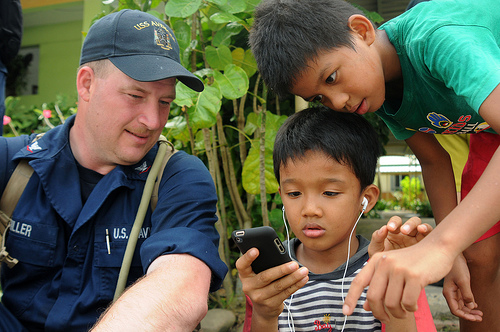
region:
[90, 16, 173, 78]
Person wearing hat on head.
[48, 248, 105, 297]
Person wearing blue shirt.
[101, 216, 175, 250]
White writing on shirt.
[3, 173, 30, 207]
Tan strap on man's shoulder.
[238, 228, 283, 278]
Person holding cell phone.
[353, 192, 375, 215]
White ear buds in child's ear.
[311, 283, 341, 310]
Child wearing striped shirt.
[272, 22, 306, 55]
Boy has dark hair.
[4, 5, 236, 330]
naval officer with cap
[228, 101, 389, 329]
young boy listening with earbuds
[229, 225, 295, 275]
smart phone held by young boy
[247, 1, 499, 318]
boy wearing turquoise shirt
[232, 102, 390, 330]
boy wearing striped shirt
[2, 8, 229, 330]
man wearing U.S.Navy shirt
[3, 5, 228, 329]
man watching boys with cell phone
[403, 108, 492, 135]
graphics on boy's tee shirt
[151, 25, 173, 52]
insignia on ball cap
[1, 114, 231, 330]
shirt with sleeves rolled up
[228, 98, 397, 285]
little boy with white headphones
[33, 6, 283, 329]
u.s. navy officer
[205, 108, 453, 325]
boy in grey and white striped shirt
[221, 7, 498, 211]
boy in green shirt and red shorts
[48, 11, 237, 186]
a blue uss navy hat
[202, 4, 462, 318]
boys trying to figure out an iphone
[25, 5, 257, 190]
green house with shrubs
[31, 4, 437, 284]
guy watching kids play with iphone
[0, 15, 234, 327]
this is a man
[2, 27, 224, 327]
man wearing navy uniform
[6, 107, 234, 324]
navy uniform is blue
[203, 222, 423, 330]
boy wearing a striped shirt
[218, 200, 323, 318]
boy holding a cell phone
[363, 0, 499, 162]
boy wearing green shirt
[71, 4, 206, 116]
man wearing blue hat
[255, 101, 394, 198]
boy with black hair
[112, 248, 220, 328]
arm of a person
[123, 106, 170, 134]
nose of a person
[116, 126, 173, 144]
mouth of a person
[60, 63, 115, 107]
ear of a person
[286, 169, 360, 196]
eye of a person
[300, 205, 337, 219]
nose of a person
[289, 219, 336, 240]
mouth of a person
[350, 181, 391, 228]
ear of a person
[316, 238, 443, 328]
hand of a person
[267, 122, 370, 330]
boy is wearing earbuds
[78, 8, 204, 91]
sailor is wearing a ball cap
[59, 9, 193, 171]
sailor is looking at the phone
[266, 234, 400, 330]
boy's shirt has stripes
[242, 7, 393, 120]
older boy is looking at the phone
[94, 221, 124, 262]
sailor has a pen in his pocket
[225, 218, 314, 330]
boy is holding the phone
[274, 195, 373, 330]
earbuds are white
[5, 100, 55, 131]
flowers behind the sailor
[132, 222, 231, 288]
sailor's sleeve is rolled up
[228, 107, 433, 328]
a young boy holding the phone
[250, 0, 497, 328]
a young boy looking at the phone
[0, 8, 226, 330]
the man sitting next to the boys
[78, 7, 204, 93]
blue hat on the man's head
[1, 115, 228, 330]
the blue shirt the man is wearing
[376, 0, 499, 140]
the green t-shirt on the boy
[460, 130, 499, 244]
the red shorts on the boy